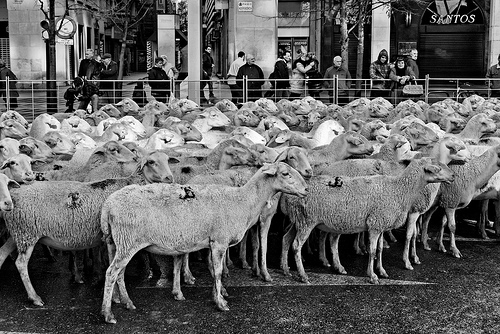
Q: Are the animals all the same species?
A: No, there are both sheep and goats.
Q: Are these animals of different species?
A: Yes, they are sheep and goats.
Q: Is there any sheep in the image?
A: Yes, there is a sheep.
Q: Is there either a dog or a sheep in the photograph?
A: Yes, there is a sheep.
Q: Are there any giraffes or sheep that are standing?
A: Yes, the sheep is standing.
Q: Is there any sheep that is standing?
A: Yes, there is a sheep that is standing.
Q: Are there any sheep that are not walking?
A: Yes, there is a sheep that is standing.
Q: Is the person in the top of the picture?
A: Yes, the person is in the top of the image.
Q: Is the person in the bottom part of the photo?
A: No, the person is in the top of the image.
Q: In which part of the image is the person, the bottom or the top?
A: The person is in the top of the image.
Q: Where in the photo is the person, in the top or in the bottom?
A: The person is in the top of the image.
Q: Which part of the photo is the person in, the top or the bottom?
A: The person is in the top of the image.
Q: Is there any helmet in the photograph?
A: No, there are no helmets.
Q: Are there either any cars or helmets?
A: No, there are no helmets or cars.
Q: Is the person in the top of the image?
A: Yes, the person is in the top of the image.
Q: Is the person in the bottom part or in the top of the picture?
A: The person is in the top of the image.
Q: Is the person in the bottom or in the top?
A: The person is in the top of the image.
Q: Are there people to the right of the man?
A: Yes, there is a person to the right of the man.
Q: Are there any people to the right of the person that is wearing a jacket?
A: Yes, there is a person to the right of the man.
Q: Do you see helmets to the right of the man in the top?
A: No, there is a person to the right of the man.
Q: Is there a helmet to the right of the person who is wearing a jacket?
A: No, there is a person to the right of the man.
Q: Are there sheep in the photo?
A: Yes, there is a sheep.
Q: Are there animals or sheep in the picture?
A: Yes, there is a sheep.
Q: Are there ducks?
A: No, there are no ducks.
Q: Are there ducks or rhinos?
A: No, there are no ducks or rhinos.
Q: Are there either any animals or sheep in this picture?
A: Yes, there is a sheep.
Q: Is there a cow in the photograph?
A: No, there are no cows.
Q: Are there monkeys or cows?
A: No, there are no cows or monkeys.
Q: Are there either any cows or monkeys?
A: No, there are no cows or monkeys.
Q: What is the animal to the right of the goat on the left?
A: The animal is a sheep.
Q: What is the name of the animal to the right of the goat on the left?
A: The animal is a sheep.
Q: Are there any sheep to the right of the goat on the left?
A: Yes, there is a sheep to the right of the goat.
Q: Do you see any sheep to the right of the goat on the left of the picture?
A: Yes, there is a sheep to the right of the goat.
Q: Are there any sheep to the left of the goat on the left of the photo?
A: No, the sheep is to the right of the goat.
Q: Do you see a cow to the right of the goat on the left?
A: No, there is a sheep to the right of the goat.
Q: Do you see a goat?
A: Yes, there is a goat.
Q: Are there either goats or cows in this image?
A: Yes, there is a goat.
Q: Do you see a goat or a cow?
A: Yes, there is a goat.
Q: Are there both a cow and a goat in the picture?
A: No, there is a goat but no cows.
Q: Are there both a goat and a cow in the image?
A: No, there is a goat but no cows.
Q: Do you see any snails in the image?
A: No, there are no snails.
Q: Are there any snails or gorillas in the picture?
A: No, there are no snails or gorillas.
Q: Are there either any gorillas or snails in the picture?
A: No, there are no snails or gorillas.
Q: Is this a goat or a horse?
A: This is a goat.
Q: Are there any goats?
A: Yes, there are goats.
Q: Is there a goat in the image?
A: Yes, there are goats.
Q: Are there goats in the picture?
A: Yes, there are goats.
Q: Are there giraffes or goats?
A: Yes, there are goats.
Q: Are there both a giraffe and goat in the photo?
A: No, there are goats but no giraffes.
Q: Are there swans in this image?
A: No, there are no swans.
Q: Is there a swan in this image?
A: No, there are no swans.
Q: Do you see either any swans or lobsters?
A: No, there are no swans or lobsters.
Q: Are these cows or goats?
A: These are goats.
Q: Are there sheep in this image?
A: Yes, there is a sheep.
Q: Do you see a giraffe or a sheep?
A: Yes, there is a sheep.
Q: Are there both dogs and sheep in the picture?
A: No, there is a sheep but no dogs.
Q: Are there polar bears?
A: No, there are no polar bears.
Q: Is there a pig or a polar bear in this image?
A: No, there are no polar bears or pigs.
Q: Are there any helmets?
A: No, there are no helmets.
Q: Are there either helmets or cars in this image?
A: No, there are no helmets or cars.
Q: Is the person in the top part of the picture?
A: Yes, the person is in the top of the image.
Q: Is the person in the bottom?
A: No, the person is in the top of the image.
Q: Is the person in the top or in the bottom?
A: The person is in the top of the image.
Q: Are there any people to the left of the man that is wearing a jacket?
A: Yes, there is a person to the left of the man.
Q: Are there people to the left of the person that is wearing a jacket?
A: Yes, there is a person to the left of the man.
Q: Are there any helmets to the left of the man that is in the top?
A: No, there is a person to the left of the man.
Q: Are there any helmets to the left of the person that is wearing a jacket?
A: No, there is a person to the left of the man.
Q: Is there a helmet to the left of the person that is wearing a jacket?
A: No, there is a person to the left of the man.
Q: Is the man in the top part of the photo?
A: Yes, the man is in the top of the image.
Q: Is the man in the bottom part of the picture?
A: No, the man is in the top of the image.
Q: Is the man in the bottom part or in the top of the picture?
A: The man is in the top of the image.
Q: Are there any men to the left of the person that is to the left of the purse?
A: Yes, there is a man to the left of the person.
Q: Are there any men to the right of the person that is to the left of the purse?
A: No, the man is to the left of the person.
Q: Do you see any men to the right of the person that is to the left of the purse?
A: No, the man is to the left of the person.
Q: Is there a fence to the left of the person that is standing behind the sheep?
A: No, there is a man to the left of the person.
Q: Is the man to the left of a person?
A: Yes, the man is to the left of a person.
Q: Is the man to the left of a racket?
A: No, the man is to the left of a person.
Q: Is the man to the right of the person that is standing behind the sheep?
A: No, the man is to the left of the person.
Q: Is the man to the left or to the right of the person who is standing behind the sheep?
A: The man is to the left of the person.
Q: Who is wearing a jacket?
A: The man is wearing a jacket.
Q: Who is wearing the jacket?
A: The man is wearing a jacket.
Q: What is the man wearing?
A: The man is wearing a jacket.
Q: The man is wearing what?
A: The man is wearing a jacket.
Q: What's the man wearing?
A: The man is wearing a jacket.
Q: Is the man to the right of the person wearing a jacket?
A: Yes, the man is wearing a jacket.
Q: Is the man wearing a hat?
A: No, the man is wearing a jacket.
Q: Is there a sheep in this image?
A: Yes, there is a sheep.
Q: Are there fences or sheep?
A: Yes, there is a sheep.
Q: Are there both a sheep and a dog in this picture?
A: No, there is a sheep but no dogs.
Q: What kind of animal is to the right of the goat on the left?
A: The animal is a sheep.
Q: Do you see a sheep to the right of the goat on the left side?
A: Yes, there is a sheep to the right of the goat.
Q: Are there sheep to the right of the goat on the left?
A: Yes, there is a sheep to the right of the goat.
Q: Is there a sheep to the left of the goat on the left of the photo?
A: No, the sheep is to the right of the goat.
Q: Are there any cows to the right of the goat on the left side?
A: No, there is a sheep to the right of the goat.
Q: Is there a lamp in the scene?
A: No, there are no lamps.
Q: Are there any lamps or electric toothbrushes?
A: No, there are no lamps or electric toothbrushes.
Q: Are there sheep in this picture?
A: Yes, there is a sheep.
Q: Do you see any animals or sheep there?
A: Yes, there is a sheep.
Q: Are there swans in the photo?
A: No, there are no swans.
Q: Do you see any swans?
A: No, there are no swans.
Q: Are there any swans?
A: No, there are no swans.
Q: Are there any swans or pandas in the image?
A: No, there are no swans or pandas.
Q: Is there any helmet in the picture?
A: No, there are no helmets.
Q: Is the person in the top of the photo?
A: Yes, the person is in the top of the image.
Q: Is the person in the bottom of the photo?
A: No, the person is in the top of the image.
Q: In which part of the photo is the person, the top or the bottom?
A: The person is in the top of the image.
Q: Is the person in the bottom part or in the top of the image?
A: The person is in the top of the image.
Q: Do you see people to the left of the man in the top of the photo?
A: Yes, there is a person to the left of the man.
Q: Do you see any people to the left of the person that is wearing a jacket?
A: Yes, there is a person to the left of the man.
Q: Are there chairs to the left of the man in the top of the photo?
A: No, there is a person to the left of the man.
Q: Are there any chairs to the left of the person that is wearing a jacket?
A: No, there is a person to the left of the man.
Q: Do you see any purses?
A: Yes, there is a purse.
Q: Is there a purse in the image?
A: Yes, there is a purse.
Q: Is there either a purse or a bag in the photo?
A: Yes, there is a purse.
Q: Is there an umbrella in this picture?
A: No, there are no umbrellas.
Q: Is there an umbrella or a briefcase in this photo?
A: No, there are no umbrellas or briefcases.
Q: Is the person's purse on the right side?
A: Yes, the purse is on the right of the image.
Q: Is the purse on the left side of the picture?
A: No, the purse is on the right of the image.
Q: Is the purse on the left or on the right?
A: The purse is on the right of the image.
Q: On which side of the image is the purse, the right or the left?
A: The purse is on the right of the image.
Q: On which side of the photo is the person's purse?
A: The purse is on the right of the image.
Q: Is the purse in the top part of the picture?
A: Yes, the purse is in the top of the image.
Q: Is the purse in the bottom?
A: No, the purse is in the top of the image.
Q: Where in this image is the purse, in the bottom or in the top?
A: The purse is in the top of the image.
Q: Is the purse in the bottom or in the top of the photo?
A: The purse is in the top of the image.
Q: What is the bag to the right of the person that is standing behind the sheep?
A: The bag is a purse.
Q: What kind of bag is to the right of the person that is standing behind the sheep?
A: The bag is a purse.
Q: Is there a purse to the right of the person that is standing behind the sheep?
A: Yes, there is a purse to the right of the person.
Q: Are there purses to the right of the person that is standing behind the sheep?
A: Yes, there is a purse to the right of the person.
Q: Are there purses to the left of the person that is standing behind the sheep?
A: No, the purse is to the right of the person.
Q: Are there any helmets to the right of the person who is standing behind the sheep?
A: No, there is a purse to the right of the person.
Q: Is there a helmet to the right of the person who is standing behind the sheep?
A: No, there is a purse to the right of the person.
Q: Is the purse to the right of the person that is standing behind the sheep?
A: Yes, the purse is to the right of the person.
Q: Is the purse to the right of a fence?
A: No, the purse is to the right of the person.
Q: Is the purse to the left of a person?
A: No, the purse is to the right of a person.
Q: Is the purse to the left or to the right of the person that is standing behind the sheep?
A: The purse is to the right of the person.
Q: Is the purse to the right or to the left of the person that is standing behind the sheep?
A: The purse is to the right of the person.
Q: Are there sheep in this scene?
A: Yes, there is a sheep.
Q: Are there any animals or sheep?
A: Yes, there is a sheep.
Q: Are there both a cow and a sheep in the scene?
A: No, there is a sheep but no cows.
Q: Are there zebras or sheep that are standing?
A: Yes, the sheep is standing.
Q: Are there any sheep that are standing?
A: Yes, there is a sheep that is standing.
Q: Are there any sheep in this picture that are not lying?
A: Yes, there is a sheep that is standing.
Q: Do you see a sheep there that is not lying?
A: Yes, there is a sheep that is standing .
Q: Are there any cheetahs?
A: No, there are no cheetahs.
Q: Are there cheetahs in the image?
A: No, there are no cheetahs.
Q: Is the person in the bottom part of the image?
A: No, the person is in the top of the image.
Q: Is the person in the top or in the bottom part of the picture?
A: The person is in the top of the image.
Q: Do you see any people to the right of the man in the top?
A: Yes, there is a person to the right of the man.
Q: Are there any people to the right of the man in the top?
A: Yes, there is a person to the right of the man.